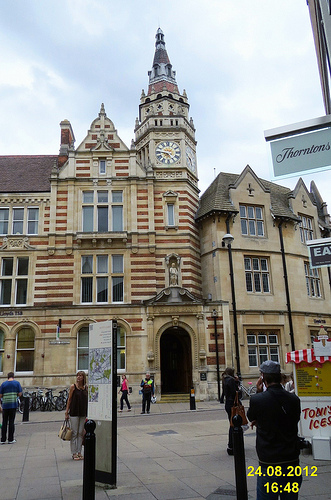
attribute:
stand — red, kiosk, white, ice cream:
[288, 328, 330, 459]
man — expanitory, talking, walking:
[247, 351, 310, 499]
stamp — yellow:
[247, 465, 315, 499]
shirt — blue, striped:
[0, 377, 23, 413]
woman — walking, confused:
[65, 372, 87, 460]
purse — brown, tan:
[57, 409, 76, 442]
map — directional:
[89, 322, 113, 423]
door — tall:
[159, 327, 191, 397]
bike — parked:
[38, 384, 53, 411]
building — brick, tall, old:
[0, 27, 225, 400]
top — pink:
[121, 378, 132, 391]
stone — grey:
[156, 452, 194, 472]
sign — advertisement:
[268, 127, 330, 176]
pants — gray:
[67, 416, 85, 453]